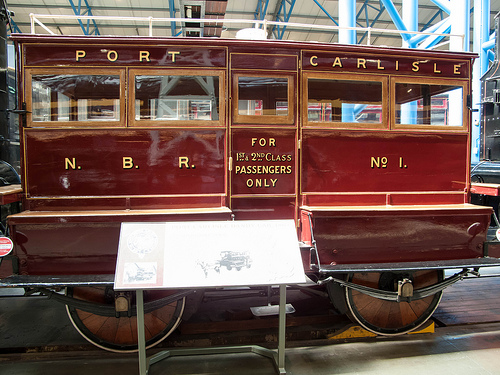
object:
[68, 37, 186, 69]
port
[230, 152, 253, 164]
1st class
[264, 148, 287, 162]
2nd class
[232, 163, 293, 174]
passengers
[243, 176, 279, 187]
only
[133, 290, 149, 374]
leg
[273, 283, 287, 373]
leg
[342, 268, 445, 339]
wheel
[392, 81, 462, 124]
window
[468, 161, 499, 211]
trim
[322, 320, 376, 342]
block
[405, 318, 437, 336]
block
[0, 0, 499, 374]
museum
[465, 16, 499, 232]
train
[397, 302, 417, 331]
hub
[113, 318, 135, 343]
hub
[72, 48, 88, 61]
letter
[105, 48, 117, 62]
letter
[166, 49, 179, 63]
letter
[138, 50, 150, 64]
letter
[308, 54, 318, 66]
letter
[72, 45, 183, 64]
port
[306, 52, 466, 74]
carlisle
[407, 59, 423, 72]
lettering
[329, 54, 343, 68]
lettering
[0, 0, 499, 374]
museum exhibit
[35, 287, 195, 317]
brace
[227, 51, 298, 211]
door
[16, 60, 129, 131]
windows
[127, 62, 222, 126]
windows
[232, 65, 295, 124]
windows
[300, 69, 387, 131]
windows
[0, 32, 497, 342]
trolley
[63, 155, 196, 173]
n.b.r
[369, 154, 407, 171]
no 1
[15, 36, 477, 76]
port carlisle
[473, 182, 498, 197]
red cart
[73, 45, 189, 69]
text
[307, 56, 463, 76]
text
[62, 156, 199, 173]
text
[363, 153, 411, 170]
text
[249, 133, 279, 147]
text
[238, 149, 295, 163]
text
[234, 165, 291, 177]
text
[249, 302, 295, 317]
step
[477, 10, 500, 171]
black train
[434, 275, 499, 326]
floor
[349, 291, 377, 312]
wooden hub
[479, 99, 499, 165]
train door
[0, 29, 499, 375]
antique trolley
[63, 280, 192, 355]
trolley wheel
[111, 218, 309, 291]
information sign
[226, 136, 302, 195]
sign on door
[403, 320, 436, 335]
wheel stops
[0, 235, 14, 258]
red sign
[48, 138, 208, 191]
car reading n.b.r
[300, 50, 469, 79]
car reading